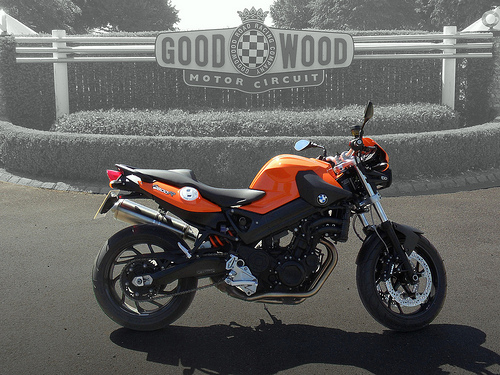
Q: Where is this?
A: This is at the street.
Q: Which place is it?
A: It is a street.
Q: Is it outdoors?
A: Yes, it is outdoors.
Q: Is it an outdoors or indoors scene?
A: It is outdoors.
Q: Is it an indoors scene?
A: No, it is outdoors.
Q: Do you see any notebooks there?
A: No, there are no notebooks.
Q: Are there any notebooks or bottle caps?
A: No, there are no notebooks or bottle caps.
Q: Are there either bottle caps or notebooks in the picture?
A: No, there are no notebooks or bottle caps.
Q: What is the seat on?
A: The seat is on the bike.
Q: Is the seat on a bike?
A: Yes, the seat is on a bike.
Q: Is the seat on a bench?
A: No, the seat is on a bike.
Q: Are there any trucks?
A: No, there are no trucks.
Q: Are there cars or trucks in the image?
A: No, there are no trucks or cars.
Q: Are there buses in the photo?
A: No, there are no buses.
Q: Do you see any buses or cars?
A: No, there are no buses or cars.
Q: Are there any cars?
A: No, there are no cars.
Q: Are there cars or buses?
A: No, there are no cars or buses.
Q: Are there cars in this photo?
A: No, there are no cars.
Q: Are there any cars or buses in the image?
A: No, there are no cars or buses.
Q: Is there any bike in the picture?
A: Yes, there is a bike.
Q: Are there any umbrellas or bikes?
A: Yes, there is a bike.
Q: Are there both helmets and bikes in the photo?
A: No, there is a bike but no helmets.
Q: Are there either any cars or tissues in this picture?
A: No, there are no cars or tissues.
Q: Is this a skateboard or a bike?
A: This is a bike.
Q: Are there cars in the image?
A: No, there are no cars.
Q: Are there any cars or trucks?
A: No, there are no cars or trucks.